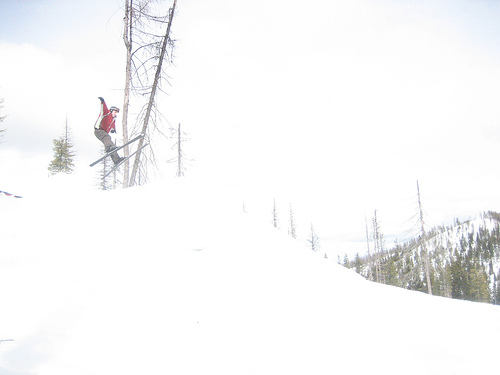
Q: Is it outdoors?
A: Yes, it is outdoors.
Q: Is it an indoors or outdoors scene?
A: It is outdoors.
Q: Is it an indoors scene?
A: No, it is outdoors.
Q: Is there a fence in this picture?
A: No, there are no fences.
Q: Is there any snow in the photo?
A: Yes, there is snow.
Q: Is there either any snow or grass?
A: Yes, there is snow.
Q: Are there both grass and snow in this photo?
A: No, there is snow but no grass.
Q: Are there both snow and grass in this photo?
A: No, there is snow but no grass.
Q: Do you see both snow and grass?
A: No, there is snow but no grass.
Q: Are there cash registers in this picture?
A: No, there are no cash registers.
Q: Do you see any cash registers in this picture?
A: No, there are no cash registers.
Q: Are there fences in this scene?
A: No, there are no fences.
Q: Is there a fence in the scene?
A: No, there are no fences.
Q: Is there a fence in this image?
A: No, there are no fences.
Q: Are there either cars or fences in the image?
A: No, there are no fences or cars.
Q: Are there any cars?
A: No, there are no cars.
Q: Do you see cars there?
A: No, there are no cars.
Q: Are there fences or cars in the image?
A: No, there are no cars or fences.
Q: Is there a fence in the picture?
A: No, there are no fences.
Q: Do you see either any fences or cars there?
A: No, there are no fences or cars.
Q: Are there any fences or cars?
A: No, there are no fences or cars.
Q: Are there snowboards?
A: No, there are no snowboards.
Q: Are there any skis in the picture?
A: Yes, there are skis.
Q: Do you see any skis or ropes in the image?
A: Yes, there are skis.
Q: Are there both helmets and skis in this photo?
A: Yes, there are both skis and a helmet.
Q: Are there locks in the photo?
A: No, there are no locks.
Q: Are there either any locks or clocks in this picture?
A: No, there are no locks or clocks.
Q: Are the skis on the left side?
A: Yes, the skis are on the left of the image.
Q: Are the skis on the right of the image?
A: No, the skis are on the left of the image.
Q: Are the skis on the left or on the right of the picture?
A: The skis are on the left of the image.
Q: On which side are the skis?
A: The skis are on the left of the image.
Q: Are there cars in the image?
A: No, there are no cars.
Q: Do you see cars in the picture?
A: No, there are no cars.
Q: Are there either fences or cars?
A: No, there are no cars or fences.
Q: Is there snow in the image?
A: Yes, there is snow.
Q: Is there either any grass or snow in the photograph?
A: Yes, there is snow.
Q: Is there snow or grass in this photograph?
A: Yes, there is snow.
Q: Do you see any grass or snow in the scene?
A: Yes, there is snow.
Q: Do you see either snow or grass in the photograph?
A: Yes, there is snow.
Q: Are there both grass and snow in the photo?
A: No, there is snow but no grass.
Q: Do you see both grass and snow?
A: No, there is snow but no grass.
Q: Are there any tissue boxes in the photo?
A: No, there are no tissue boxes.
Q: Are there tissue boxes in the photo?
A: No, there are no tissue boxes.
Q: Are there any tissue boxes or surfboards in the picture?
A: No, there are no tissue boxes or surfboards.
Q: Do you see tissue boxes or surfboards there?
A: No, there are no tissue boxes or surfboards.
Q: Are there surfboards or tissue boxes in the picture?
A: No, there are no tissue boxes or surfboards.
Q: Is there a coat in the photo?
A: Yes, there is a coat.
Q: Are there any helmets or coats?
A: Yes, there is a coat.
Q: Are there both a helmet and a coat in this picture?
A: Yes, there are both a coat and a helmet.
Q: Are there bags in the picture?
A: No, there are no bags.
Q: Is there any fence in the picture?
A: No, there are no fences.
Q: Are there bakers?
A: No, there are no bakers.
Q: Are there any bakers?
A: No, there are no bakers.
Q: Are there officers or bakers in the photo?
A: No, there are no bakers or officers.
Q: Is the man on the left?
A: Yes, the man is on the left of the image.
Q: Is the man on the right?
A: No, the man is on the left of the image.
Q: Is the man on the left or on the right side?
A: The man is on the left of the image.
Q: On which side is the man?
A: The man is on the left of the image.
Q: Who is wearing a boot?
A: The man is wearing a boot.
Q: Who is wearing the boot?
A: The man is wearing a boot.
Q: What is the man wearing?
A: The man is wearing a boot.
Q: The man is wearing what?
A: The man is wearing a boot.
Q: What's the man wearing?
A: The man is wearing a boot.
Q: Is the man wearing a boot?
A: Yes, the man is wearing a boot.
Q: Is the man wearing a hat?
A: No, the man is wearing a boot.